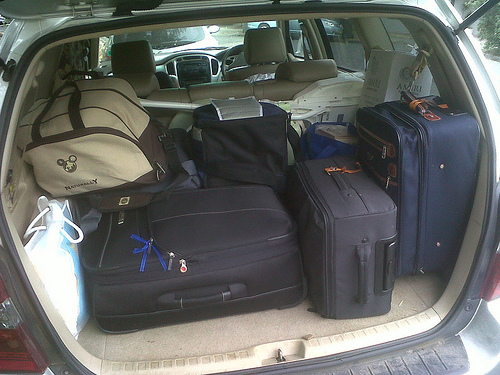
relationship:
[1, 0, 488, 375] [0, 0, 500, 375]
cargo area of car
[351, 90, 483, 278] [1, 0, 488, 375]
luggage piece in cargo area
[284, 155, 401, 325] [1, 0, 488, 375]
suitcase in cargo area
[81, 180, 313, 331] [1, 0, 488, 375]
luggage piece in cargo area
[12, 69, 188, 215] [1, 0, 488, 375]
backpack in cargo area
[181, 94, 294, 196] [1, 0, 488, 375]
suitcase in cargo area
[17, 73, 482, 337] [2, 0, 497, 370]
luggage in car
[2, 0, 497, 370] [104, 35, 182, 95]
car has driver seat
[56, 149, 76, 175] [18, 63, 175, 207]
design on back of backpack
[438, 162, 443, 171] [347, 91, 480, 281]
rivet on side of luggage